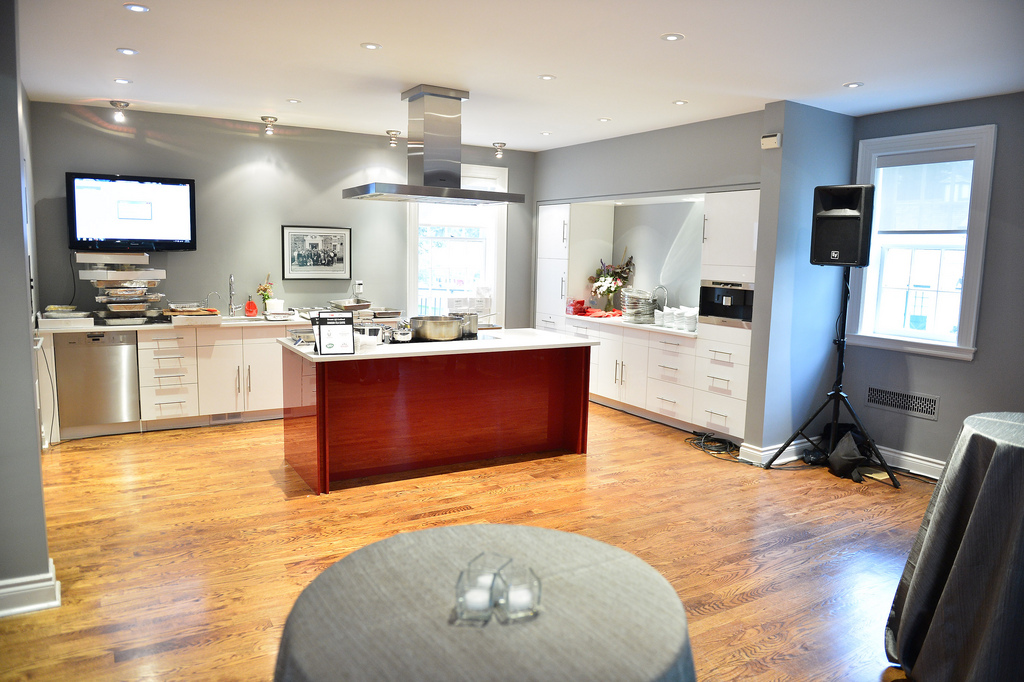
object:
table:
[284, 523, 687, 672]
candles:
[457, 549, 498, 622]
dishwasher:
[49, 325, 136, 440]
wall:
[766, 106, 1001, 470]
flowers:
[577, 256, 642, 293]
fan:
[341, 69, 522, 205]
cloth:
[277, 513, 699, 672]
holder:
[496, 567, 535, 623]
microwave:
[693, 278, 758, 322]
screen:
[72, 173, 197, 246]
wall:
[942, 382, 1005, 470]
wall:
[27, 99, 541, 331]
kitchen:
[0, 3, 1021, 677]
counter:
[564, 297, 758, 439]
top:
[280, 313, 595, 359]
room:
[232, 17, 1024, 678]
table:
[881, 408, 1023, 678]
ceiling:
[20, 0, 1022, 155]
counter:
[531, 225, 737, 372]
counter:
[281, 326, 588, 493]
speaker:
[814, 178, 871, 269]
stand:
[765, 267, 897, 494]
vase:
[607, 290, 621, 316]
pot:
[454, 310, 474, 337]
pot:
[383, 321, 410, 339]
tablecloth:
[900, 440, 1015, 654]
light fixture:
[104, 101, 128, 127]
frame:
[281, 223, 357, 278]